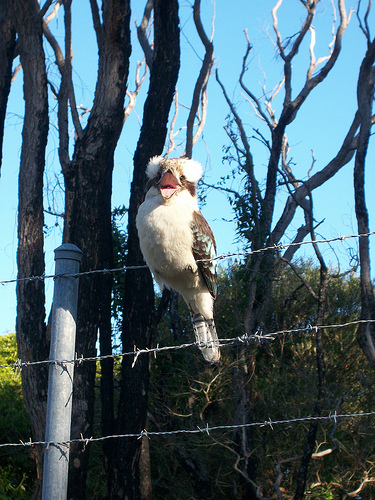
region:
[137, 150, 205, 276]
this is a bird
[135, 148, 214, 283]
the bird is motionless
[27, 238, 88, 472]
this is a pole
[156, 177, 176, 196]
the beak is big in size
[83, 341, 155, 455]
this is the fence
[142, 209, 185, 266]
the bird is white in color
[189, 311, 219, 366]
the tail is long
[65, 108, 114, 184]
this is a tree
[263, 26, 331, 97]
the branches are dry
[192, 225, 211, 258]
the feather is folded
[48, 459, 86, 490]
the post is steel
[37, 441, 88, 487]
the post is steel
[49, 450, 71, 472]
the post is steel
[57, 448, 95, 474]
the post is steel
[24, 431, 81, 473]
the post is steel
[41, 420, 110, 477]
the post is steel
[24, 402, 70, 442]
the post is steel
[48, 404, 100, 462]
the post is steel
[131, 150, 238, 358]
a bird chirs on a fence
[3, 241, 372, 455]
a barbed wire fence keeps predators out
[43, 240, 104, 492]
a metal pole connects the barbed wire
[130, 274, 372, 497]
shrubbery covers the fence line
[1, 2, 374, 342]
the trees are dying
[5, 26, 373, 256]
the sky has no clouds in sight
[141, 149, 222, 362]
the bird has fluffy feathers on his head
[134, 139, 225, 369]
the bird has stripes on his feathers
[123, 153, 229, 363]
the bird is shades of brown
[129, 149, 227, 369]
the bird has a large beak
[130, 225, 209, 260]
the bird feather is white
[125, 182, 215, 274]
the bird feather is white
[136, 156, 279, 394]
the bird feather is white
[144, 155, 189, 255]
the bird feather is white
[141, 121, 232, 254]
the bird feather is white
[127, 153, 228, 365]
a bird on a fence.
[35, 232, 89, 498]
a barbed wire fence pole.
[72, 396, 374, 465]
a line of barbed wire.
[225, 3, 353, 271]
a tree with no leaves.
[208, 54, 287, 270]
a leaf filled tree.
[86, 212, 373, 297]
a bird on a strand of barbed wire.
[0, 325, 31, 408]
a tree with lush green leaves.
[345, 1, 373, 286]
a tree branch near a forest.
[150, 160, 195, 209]
a bird with an open beak.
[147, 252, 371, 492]
a tree with lots of green.